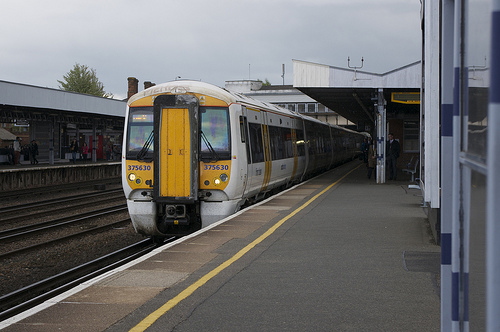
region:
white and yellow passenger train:
[126, 69, 298, 193]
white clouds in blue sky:
[12, 8, 87, 35]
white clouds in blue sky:
[52, 9, 116, 46]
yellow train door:
[143, 101, 200, 195]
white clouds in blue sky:
[171, 10, 223, 51]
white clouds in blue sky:
[226, 17, 268, 69]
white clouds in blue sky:
[281, 13, 326, 51]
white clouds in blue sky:
[324, 15, 375, 57]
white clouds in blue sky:
[151, 15, 197, 52]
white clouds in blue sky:
[27, 25, 91, 48]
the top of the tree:
[56, 61, 115, 98]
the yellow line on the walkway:
[126, 160, 370, 330]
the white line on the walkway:
[0, 170, 324, 330]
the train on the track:
[120, 80, 373, 237]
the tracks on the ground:
[0, 183, 150, 330]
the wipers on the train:
[136, 128, 218, 162]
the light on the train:
[129, 173, 135, 180]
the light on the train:
[213, 178, 220, 185]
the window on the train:
[126, 105, 154, 160]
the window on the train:
[198, 105, 230, 161]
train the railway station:
[119, 71, 254, 231]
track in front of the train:
[29, 191, 141, 278]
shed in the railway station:
[2, 80, 131, 133]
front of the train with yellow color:
[125, 85, 232, 236]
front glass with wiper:
[125, 108, 233, 165]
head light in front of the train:
[129, 168, 232, 192]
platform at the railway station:
[179, 178, 354, 326]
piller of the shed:
[374, 92, 393, 188]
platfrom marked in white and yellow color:
[91, 178, 287, 330]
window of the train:
[248, 118, 268, 167]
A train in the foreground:
[110, 71, 370, 251]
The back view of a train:
[118, 81, 250, 251]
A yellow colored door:
[148, 95, 200, 200]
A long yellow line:
[115, 160, 376, 325]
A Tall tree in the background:
[55, 55, 113, 107]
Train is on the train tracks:
[117, 60, 367, 272]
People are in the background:
[1, 126, 41, 161]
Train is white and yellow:
[116, 62, 371, 242]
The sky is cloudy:
[0, 2, 422, 92]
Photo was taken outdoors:
[2, 0, 498, 326]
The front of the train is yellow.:
[122, 90, 224, 229]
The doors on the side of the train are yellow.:
[259, 107, 274, 197]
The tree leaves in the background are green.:
[61, 64, 106, 90]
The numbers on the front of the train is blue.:
[129, 164, 153, 170]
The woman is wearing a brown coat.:
[366, 137, 379, 178]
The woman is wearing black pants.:
[370, 138, 379, 179]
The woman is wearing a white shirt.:
[365, 136, 379, 184]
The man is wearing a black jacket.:
[386, 131, 399, 180]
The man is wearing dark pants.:
[387, 134, 403, 182]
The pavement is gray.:
[307, 246, 387, 316]